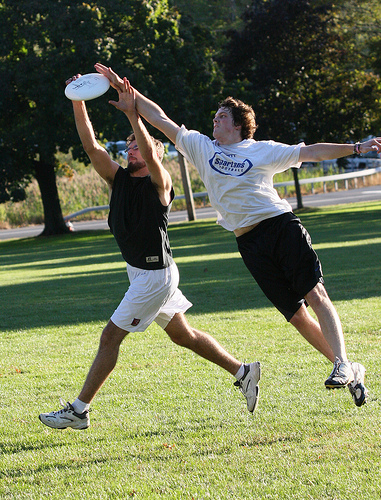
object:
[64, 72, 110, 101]
frisbee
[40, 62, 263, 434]
man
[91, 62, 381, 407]
man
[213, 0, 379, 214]
trees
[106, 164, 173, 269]
t-shirt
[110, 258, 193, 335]
shorts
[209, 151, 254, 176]
logo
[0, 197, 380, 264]
shadows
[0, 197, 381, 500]
grass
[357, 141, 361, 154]
bracelets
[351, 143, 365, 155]
wrist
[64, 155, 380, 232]
guard rail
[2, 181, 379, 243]
street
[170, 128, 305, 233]
shirt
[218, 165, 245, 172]
letters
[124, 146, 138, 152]
glasses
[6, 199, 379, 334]
shade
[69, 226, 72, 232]
hydrant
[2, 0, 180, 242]
tree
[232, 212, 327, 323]
shorts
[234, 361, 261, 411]
tennis shoes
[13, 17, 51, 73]
leaves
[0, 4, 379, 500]
air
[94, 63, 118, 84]
hand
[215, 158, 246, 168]
graphics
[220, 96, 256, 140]
hair